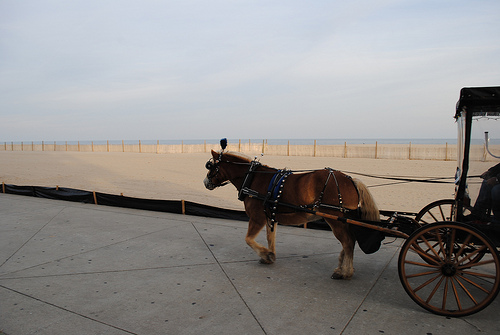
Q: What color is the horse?
A: Brown.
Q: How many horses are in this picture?
A: One.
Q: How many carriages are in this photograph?
A: One.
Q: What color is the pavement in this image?
A: Grey.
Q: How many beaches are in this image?
A: One.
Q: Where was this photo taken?
A: On a beach.